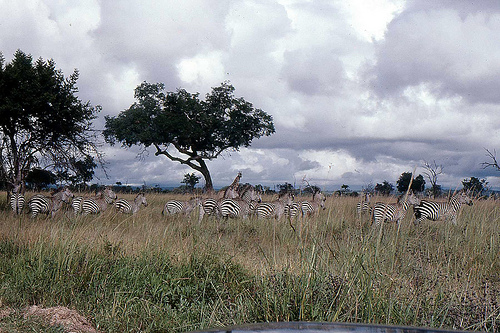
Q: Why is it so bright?
A: Sunny.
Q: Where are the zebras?
A: The grass.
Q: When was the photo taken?
A: Day time.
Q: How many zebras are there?
A: Dozens.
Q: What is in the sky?
A: Clouds.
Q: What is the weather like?
A: Clear skies.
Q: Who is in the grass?
A: Zebras.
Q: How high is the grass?
A: Mid length.